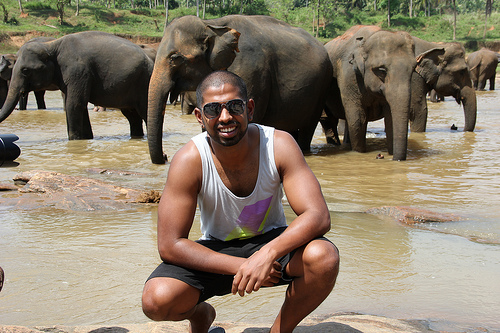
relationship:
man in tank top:
[140, 71, 341, 333] [175, 135, 255, 242]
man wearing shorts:
[140, 71, 341, 333] [136, 230, 346, 292]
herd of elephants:
[11, 7, 493, 170] [92, 19, 466, 115]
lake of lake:
[0, 51, 500, 330] [0, 51, 500, 330]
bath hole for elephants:
[31, 115, 125, 235] [12, 30, 479, 136]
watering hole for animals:
[290, 127, 473, 285] [56, 27, 481, 141]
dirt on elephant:
[143, 60, 178, 130] [145, 15, 335, 151]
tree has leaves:
[381, 2, 398, 32] [391, 13, 415, 25]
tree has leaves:
[381, 2, 398, 32] [314, 19, 337, 37]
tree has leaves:
[381, 2, 398, 32] [211, 1, 271, 14]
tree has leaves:
[381, 2, 398, 32] [26, 1, 57, 17]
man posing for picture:
[164, 66, 292, 211] [84, 45, 432, 310]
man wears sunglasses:
[140, 71, 341, 333] [201, 97, 246, 119]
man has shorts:
[140, 71, 341, 333] [141, 223, 292, 295]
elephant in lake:
[325, 23, 420, 160] [0, 51, 500, 330]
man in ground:
[140, 71, 341, 333] [334, 312, 415, 327]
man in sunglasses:
[140, 71, 341, 333] [199, 97, 247, 121]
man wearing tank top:
[140, 71, 341, 333] [184, 124, 299, 265]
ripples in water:
[340, 163, 493, 205] [367, 148, 460, 187]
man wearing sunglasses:
[140, 71, 341, 333] [185, 93, 250, 123]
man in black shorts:
[140, 71, 341, 333] [146, 225, 313, 298]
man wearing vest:
[140, 71, 341, 333] [185, 117, 295, 246]